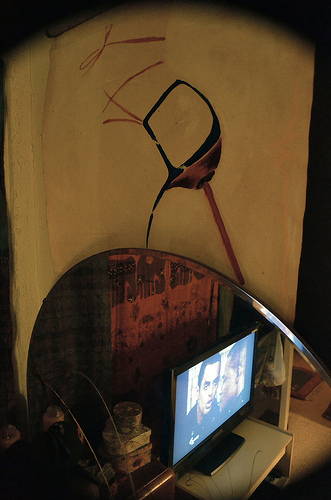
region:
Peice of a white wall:
[15, 107, 35, 128]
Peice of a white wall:
[9, 249, 52, 279]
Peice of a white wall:
[36, 221, 83, 249]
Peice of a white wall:
[59, 182, 118, 230]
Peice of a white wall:
[250, 202, 297, 264]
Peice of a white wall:
[246, 97, 280, 161]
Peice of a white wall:
[31, 199, 86, 222]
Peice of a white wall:
[28, 163, 73, 201]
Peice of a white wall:
[6, 269, 70, 343]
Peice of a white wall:
[4, 303, 41, 349]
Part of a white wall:
[11, 215, 38, 246]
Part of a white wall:
[4, 246, 35, 281]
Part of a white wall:
[7, 293, 24, 318]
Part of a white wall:
[6, 321, 26, 352]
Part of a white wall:
[29, 246, 58, 280]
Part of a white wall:
[23, 191, 69, 251]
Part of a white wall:
[20, 169, 58, 203]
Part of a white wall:
[58, 187, 89, 229]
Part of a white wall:
[250, 241, 314, 316]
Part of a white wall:
[146, 196, 257, 264]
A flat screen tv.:
[161, 322, 257, 477]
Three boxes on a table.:
[97, 400, 152, 477]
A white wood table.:
[176, 414, 294, 497]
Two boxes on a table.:
[100, 399, 152, 457]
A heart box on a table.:
[100, 414, 151, 456]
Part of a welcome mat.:
[289, 364, 323, 401]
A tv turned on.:
[162, 321, 258, 477]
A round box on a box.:
[111, 399, 143, 429]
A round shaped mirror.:
[25, 246, 328, 499]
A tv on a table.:
[162, 319, 295, 498]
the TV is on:
[157, 331, 273, 469]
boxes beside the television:
[108, 395, 170, 490]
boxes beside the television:
[95, 346, 227, 495]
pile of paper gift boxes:
[101, 398, 154, 478]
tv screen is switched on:
[155, 317, 264, 484]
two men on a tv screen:
[194, 343, 248, 421]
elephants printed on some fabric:
[104, 246, 219, 311]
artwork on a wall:
[77, 17, 256, 287]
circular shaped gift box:
[110, 396, 143, 428]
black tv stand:
[187, 428, 249, 479]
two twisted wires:
[39, 366, 138, 498]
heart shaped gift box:
[99, 411, 151, 458]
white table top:
[168, 412, 295, 496]